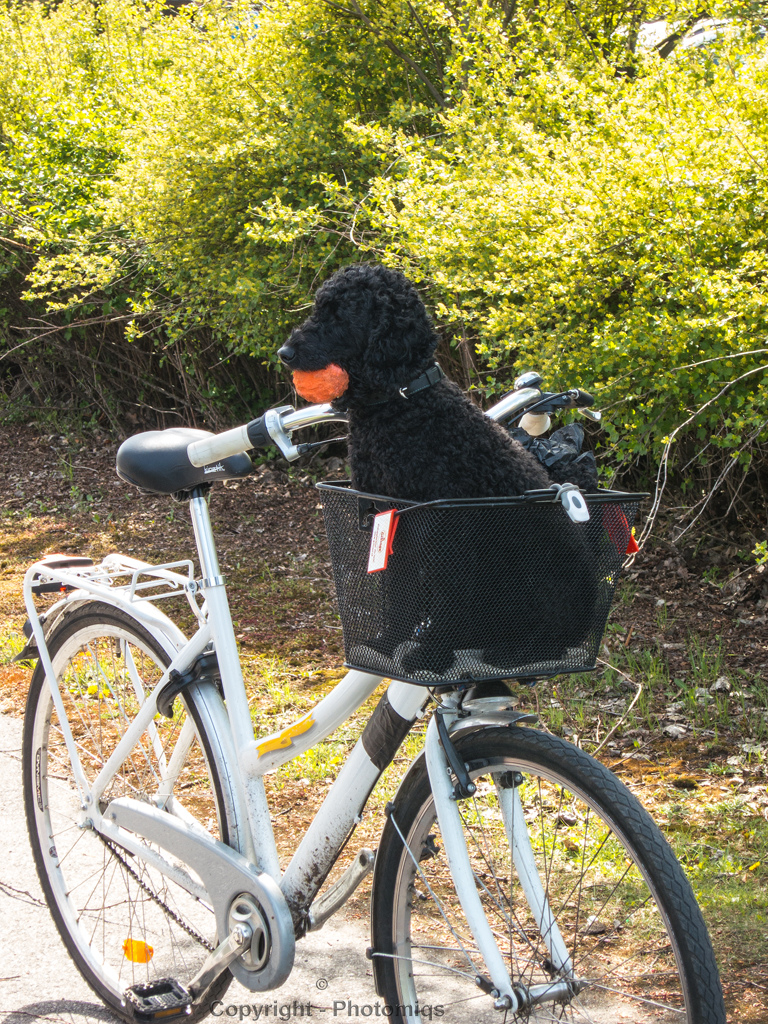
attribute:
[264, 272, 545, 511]
dog — black, basket, cute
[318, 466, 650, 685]
basket — black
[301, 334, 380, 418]
ball — orange, pink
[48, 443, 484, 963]
bike — white, locked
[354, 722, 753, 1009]
tire — black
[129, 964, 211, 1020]
pedal — black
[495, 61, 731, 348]
folliage — green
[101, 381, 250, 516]
seat — black, raised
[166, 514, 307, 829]
frame — white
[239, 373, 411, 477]
handlebar — white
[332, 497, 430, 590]
tag — adress tag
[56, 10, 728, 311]
background — beautiful